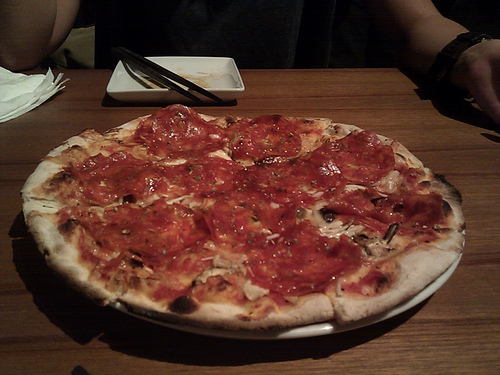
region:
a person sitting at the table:
[1, 1, 478, 90]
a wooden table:
[8, 65, 471, 363]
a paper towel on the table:
[8, 71, 62, 116]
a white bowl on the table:
[103, 53, 239, 92]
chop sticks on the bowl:
[114, 47, 211, 101]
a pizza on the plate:
[43, 120, 474, 317]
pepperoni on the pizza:
[223, 115, 304, 146]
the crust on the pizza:
[368, 263, 413, 278]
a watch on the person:
[426, 28, 498, 88]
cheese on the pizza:
[109, 137, 149, 142]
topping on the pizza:
[287, 225, 361, 265]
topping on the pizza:
[165, 236, 218, 289]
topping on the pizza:
[137, 251, 164, 286]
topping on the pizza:
[207, 203, 238, 243]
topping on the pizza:
[261, 209, 298, 251]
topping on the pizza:
[272, 200, 311, 243]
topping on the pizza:
[135, 209, 168, 242]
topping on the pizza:
[270, 160, 319, 202]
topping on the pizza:
[138, 172, 186, 209]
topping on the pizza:
[264, 170, 314, 219]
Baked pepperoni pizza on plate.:
[22, 105, 463, 339]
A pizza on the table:
[45, 74, 482, 345]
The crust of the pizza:
[38, 253, 431, 333]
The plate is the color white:
[95, 286, 462, 341]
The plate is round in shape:
[121, 301, 439, 338]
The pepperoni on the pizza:
[114, 188, 349, 285]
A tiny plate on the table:
[101, 39, 252, 114]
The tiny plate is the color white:
[98, 62, 253, 102]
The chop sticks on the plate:
[106, 40, 228, 107]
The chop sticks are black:
[117, 32, 200, 107]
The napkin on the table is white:
[2, 63, 74, 130]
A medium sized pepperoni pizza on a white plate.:
[15, 99, 475, 344]